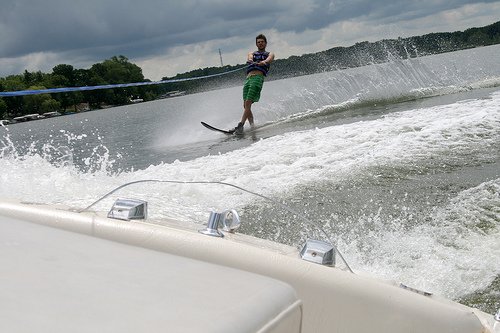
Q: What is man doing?
A: Water skiing.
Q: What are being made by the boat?
A: Waves.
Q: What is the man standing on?
A: Water ski.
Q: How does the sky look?
A: Cloudy.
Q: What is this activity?
A: Waterskiing.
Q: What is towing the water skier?
A: A boat.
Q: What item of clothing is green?
A: Shorts.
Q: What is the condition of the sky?
A: Dark and cloudy.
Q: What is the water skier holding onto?
A: Rope.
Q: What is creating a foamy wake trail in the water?
A: The boat.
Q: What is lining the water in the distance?
A: Trees.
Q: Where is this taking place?
A: In a lake.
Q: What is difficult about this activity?
A: Staying upright.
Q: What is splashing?
A: The water.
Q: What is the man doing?
A: Water skiing.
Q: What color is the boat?
A: White.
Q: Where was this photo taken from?
A: On a boat.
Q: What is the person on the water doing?
A: Water skiing.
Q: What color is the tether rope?
A: Blue.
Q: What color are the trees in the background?
A: Green.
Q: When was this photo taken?
A: Outside during the day.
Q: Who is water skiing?
A: The person in green shorts.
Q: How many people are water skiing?
A: One.